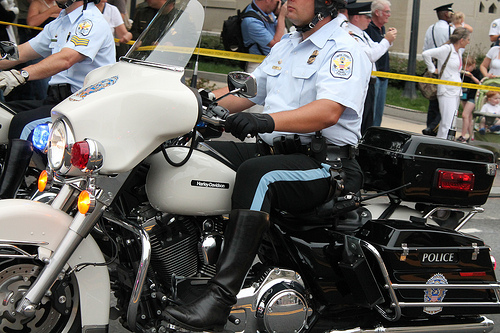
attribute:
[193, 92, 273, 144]
gloves — black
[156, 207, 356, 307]
boots — black, leather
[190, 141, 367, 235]
pants — black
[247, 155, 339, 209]
stripe — blue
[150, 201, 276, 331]
boots — calf-high, black, leather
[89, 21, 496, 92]
caution tape — yellow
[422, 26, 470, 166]
woman — dressed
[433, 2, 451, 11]
cap — black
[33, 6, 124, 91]
shirt — striped